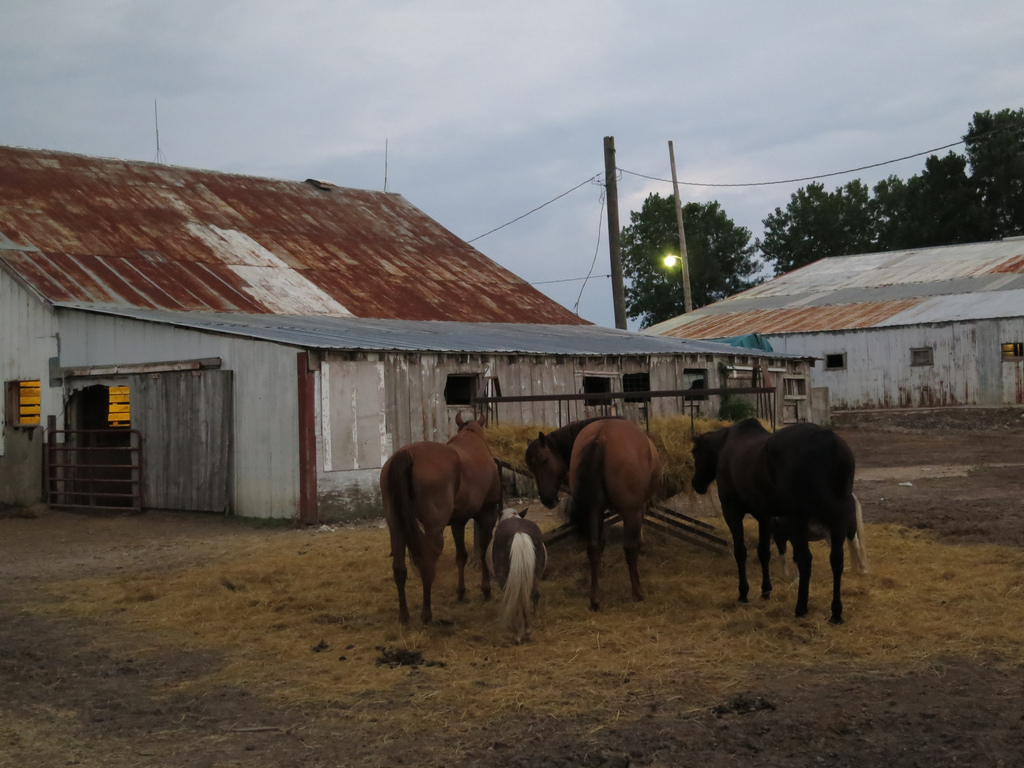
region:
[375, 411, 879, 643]
three horses and a pony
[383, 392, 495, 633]
a brown horse feeding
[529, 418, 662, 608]
a brown horse with a black mane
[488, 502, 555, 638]
a grey pony with a white tail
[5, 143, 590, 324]
a rusted tin roof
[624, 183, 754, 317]
leaves on a tree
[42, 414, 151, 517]
a gate in front of a door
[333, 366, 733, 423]
windows on the side of a barn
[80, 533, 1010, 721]
hay that is on the ground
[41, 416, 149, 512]
metal gate in front of doorway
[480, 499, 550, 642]
small horse with white tail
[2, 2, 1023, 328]
gray overcast sky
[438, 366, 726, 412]
small windows in barn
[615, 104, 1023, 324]
green trees behind the building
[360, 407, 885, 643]
horses gathered around hay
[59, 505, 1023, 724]
hay on the ground around the horses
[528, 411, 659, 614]
brown horse looking back at small horse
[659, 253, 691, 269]
small light on wooden pole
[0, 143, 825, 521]
tin roof on barn is rusty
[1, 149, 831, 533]
barn has wooden sliding door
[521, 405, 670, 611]
brown horse is looking back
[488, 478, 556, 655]
brown and white pony has long tail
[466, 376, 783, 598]
hay in black metal feeder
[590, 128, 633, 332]
tall wooden power pole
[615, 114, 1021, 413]
trees behind white barn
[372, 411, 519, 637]
brown horse has black tail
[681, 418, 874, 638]
dark brown horse is standing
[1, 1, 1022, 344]
sky is gray and overcast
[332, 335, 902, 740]
Four horses eating hay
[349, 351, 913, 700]
Horses eating in barnyard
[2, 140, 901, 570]
Rusted metal building in barn yard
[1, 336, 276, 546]
Metal gate on rusted metal building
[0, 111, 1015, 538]
Two metal buildings that are rusted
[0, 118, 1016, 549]
Two weather worn metal buildings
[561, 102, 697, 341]
Two wooden electrical posts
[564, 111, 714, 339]
Two wooden electrical poles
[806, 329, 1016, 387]
Three windows on metal farm building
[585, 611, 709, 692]
the hay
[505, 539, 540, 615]
a white tail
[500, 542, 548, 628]
the tail on the horse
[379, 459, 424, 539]
a black tail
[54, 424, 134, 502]
a small gate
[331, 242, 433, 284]
the rooftop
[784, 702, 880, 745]
mud in the grass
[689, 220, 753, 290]
a green bush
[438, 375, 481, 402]
building has a window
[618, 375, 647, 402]
building has a window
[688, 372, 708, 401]
building has a window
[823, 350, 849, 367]
building has a window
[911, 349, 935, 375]
building has a window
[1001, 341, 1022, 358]
building has a window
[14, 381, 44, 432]
building has a window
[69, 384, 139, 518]
building has a window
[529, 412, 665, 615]
a brown h orse with a black mane is in the middle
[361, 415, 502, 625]
there is a brown horse at the end by the hay trough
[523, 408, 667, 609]
the horse in the center looks at the pony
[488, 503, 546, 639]
a small pony stands by a hay trough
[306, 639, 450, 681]
a large pile of manure is behind the brown horse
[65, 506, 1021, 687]
the hay on the ground is fresh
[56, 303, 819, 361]
the metal roof is new and unrusted